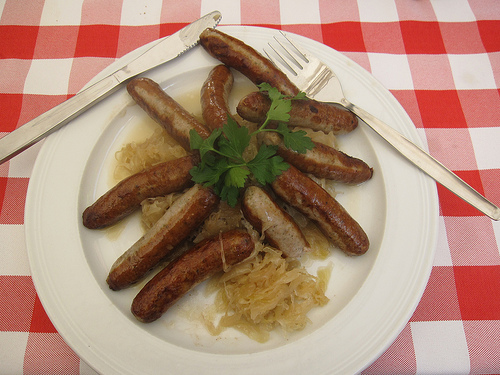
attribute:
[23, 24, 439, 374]
plate — white, shallow, round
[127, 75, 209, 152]
sausage — brown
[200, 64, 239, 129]
sausage — brown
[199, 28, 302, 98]
sausage — tasty, link, small, meal, brown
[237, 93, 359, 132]
sausage — brown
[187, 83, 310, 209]
parsley — decoration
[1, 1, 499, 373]
tablecloth — checkered, white, red, plaid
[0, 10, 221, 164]
knife — serrated, silver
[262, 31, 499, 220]
fork — silver, white